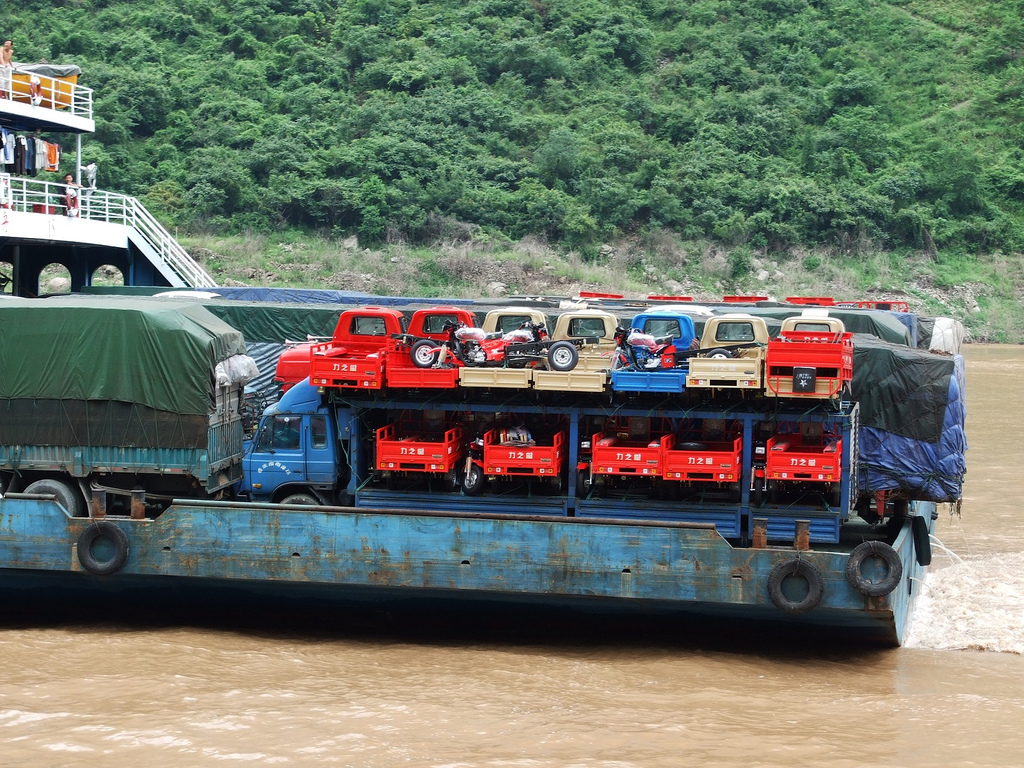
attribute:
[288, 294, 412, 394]
truck — red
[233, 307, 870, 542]
truck — blue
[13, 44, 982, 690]
ship — large